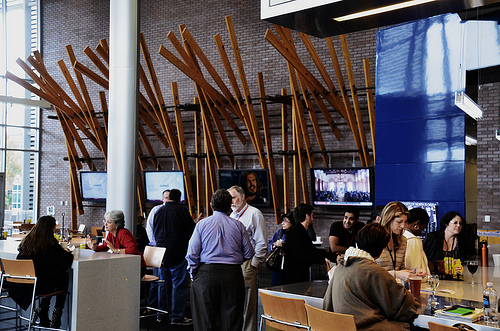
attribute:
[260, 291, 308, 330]
chair — wooden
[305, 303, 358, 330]
chair — wooden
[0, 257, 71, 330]
chair — wooden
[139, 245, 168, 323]
chair — wooden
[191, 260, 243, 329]
trousers — dark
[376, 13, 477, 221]
board — blue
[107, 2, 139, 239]
pole — white, large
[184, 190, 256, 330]
man — standing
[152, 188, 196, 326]
man — standing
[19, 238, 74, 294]
woman — sitting, talking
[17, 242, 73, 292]
shirt — black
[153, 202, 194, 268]
shirt — black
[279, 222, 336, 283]
shirt — black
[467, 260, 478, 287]
wine — red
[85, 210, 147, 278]
woman — sitting, talking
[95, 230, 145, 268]
shirt — red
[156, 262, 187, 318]
jeans — blue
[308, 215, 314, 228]
beard — black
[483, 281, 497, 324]
water bottle — plastic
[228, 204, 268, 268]
dress shirt — white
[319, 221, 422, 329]
woman — sitting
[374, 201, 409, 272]
woman — sitting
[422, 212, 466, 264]
woman — sitting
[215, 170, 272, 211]
television — flat screen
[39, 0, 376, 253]
wall — red, brick, high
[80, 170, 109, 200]
television — flat screen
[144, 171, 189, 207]
television — flat screen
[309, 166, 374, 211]
television — flat screen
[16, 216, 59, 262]
hair — long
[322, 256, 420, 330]
coat — tan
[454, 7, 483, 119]
light — suspended, hanging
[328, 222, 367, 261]
shirt — black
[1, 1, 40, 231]
windows — large, tall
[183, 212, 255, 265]
shirt — purple